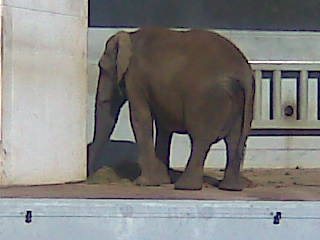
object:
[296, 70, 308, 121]
bar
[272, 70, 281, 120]
bar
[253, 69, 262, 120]
bar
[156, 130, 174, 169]
leg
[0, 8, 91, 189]
wall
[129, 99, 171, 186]
leg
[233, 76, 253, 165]
tail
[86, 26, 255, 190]
elephant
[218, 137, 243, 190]
leg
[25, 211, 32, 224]
mark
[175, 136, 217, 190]
elephant leg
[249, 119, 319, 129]
bar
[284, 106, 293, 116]
hole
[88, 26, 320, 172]
wall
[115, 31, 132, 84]
ear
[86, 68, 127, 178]
trunk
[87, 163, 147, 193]
grass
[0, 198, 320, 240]
wall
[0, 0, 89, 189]
surface